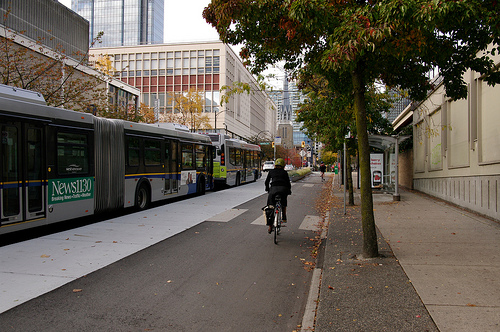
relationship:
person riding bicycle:
[267, 154, 294, 193] [261, 200, 294, 246]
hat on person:
[273, 156, 286, 171] [267, 154, 294, 193]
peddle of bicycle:
[279, 223, 286, 226] [261, 200, 294, 246]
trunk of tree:
[347, 88, 390, 266] [216, 1, 443, 280]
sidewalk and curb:
[18, 215, 176, 277] [36, 225, 88, 232]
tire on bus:
[128, 174, 156, 212] [3, 82, 260, 211]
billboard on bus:
[48, 172, 106, 204] [2, 87, 108, 224]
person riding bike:
[267, 154, 294, 193] [261, 200, 294, 246]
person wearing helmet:
[267, 154, 294, 193] [273, 156, 286, 171]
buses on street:
[3, 82, 260, 211] [2, 48, 242, 270]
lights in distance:
[250, 127, 290, 148] [222, 86, 349, 153]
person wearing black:
[267, 154, 294, 193] [270, 174, 282, 195]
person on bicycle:
[267, 154, 294, 193] [261, 200, 294, 246]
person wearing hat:
[267, 154, 294, 193] [273, 156, 286, 171]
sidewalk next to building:
[18, 215, 176, 277] [2, 3, 150, 114]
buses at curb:
[3, 82, 260, 211] [36, 225, 88, 232]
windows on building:
[137, 56, 217, 92] [2, 3, 150, 114]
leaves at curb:
[304, 227, 320, 273] [36, 225, 88, 232]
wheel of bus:
[128, 174, 156, 212] [2, 87, 108, 224]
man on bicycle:
[267, 154, 294, 193] [261, 200, 294, 246]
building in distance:
[110, 40, 284, 118] [222, 86, 349, 153]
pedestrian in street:
[320, 158, 331, 189] [2, 48, 242, 270]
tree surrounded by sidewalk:
[216, 1, 443, 280] [18, 215, 176, 277]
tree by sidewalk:
[216, 1, 443, 280] [18, 215, 176, 277]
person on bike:
[267, 154, 294, 193] [261, 200, 294, 246]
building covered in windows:
[110, 40, 284, 118] [137, 56, 217, 92]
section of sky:
[169, 15, 192, 32] [167, 3, 201, 38]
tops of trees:
[213, 1, 482, 39] [216, 1, 443, 280]